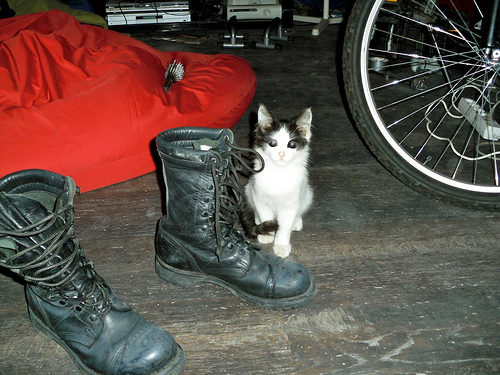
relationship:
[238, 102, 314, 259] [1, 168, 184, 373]
cat near boot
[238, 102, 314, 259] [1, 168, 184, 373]
cat next to boot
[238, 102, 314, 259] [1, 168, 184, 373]
cat close to boot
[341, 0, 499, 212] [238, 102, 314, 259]
bicycle wheel next to cat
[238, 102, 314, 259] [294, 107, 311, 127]
cat has a ears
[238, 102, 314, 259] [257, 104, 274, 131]
cat has a right ear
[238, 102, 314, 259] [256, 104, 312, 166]
cat has a head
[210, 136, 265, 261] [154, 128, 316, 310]
laces on boot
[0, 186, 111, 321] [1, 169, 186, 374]
laces on boot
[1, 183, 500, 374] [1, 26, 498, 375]
scratches on floor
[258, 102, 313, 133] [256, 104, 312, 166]
ears on head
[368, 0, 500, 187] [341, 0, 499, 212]
spokes on bicycle wheel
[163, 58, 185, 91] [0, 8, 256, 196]
hairbrush on cushion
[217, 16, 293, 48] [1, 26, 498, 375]
push up bars on floor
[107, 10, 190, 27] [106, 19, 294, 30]
stereo on shelf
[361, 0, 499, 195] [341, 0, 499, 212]
stripe on bicycle wheel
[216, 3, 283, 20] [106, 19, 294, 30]
xbox 360 on shelf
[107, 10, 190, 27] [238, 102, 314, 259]
stereo behind cat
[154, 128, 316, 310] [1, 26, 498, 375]
boot on floor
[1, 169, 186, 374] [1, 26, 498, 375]
boot on floor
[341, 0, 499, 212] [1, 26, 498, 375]
bicycle wheel on floor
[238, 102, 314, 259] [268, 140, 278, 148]
cat has right eye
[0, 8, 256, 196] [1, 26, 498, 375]
cushion on floor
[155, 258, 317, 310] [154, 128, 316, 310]
sole of boot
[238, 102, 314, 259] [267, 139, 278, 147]
cat has a right eye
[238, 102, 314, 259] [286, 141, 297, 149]
cat has a left eye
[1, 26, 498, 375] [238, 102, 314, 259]
floor under cat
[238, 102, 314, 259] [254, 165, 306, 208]
cat has a chest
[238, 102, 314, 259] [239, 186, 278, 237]
cat has a tail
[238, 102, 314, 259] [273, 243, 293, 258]
cat has a left paw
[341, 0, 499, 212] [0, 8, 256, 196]
bicycle wheel near cushion